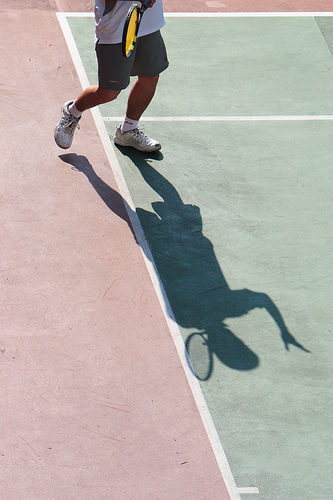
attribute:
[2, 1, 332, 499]
court — green, marked, red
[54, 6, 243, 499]
line — white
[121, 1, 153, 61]
racket — black, stringed, yellow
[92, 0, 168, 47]
shirt — white, green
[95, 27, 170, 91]
shorts — grey, red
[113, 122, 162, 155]
shoe — white, lifted, up, red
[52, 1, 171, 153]
person — playing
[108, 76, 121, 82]
logo — tiny, white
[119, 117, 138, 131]
sock — white